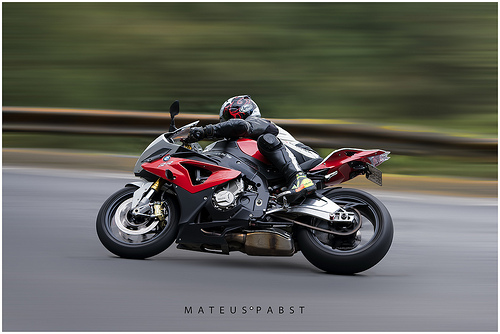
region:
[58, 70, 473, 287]
This looks like a race.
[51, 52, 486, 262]
This man could be a racer.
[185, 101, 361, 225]
The man has on protective gear.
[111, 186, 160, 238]
The rims are made of metal.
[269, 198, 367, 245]
The bike has a large chain.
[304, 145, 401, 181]
The tail of the bike is red.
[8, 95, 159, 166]
The railing is made of metal.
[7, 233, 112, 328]
The ground is gray in color.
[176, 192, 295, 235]
The middle of the bike is black.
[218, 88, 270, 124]
The helmet is black, white, and red.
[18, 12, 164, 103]
The background is green.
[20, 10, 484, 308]
The background is blurry.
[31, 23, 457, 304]
This is a photo of movement.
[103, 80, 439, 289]
This is a motorcycle.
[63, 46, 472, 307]
The man is going very fast.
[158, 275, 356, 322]
This photo is watermarked.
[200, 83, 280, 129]
The man has on a helmet.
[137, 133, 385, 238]
The bike is black and red.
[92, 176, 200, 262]
This is the front tire.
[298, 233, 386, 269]
The tires are made of rubber.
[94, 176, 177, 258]
Front motorcycle wheel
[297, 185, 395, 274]
Back motorcycle wheel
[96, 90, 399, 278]
Man riding fast on a motorcycle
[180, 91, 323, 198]
Man in motorcycle gear and helmet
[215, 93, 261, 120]
Black, white and red motorcycle helmet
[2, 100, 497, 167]
Iron metal railing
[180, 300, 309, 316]
Company name and logo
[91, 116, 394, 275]
Red and black motorcycle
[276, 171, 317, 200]
Black red and white shoe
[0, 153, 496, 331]
Concrete road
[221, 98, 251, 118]
design on side of motorcycle helmet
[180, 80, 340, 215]
person driving motorcycle on road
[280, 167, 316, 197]
green design on black boot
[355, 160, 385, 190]
license plate on back of motorcycle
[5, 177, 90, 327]
grey pavement on road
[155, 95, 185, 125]
black side mirror on motorcycle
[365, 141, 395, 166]
tail light on back of motorcycle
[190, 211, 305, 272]
silver metal gas tank of motorcycle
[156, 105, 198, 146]
clear bug guard on front of motorcycle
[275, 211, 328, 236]
silver metal motorcycle chain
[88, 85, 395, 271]
motorcyclist speeding on road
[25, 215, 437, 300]
black wheels on smooth gray surface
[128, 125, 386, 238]
black and red motorcycle with jutting panels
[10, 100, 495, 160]
railing on side of motorcycle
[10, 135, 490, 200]
curb on edge of road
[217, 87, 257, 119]
graphics on red, black and white helmet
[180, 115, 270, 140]
black sleeve and glove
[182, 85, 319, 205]
knee lifted nearly to armpit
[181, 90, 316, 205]
driver leaning forward against motorcycle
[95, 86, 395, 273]
motorcyclist leaning to right